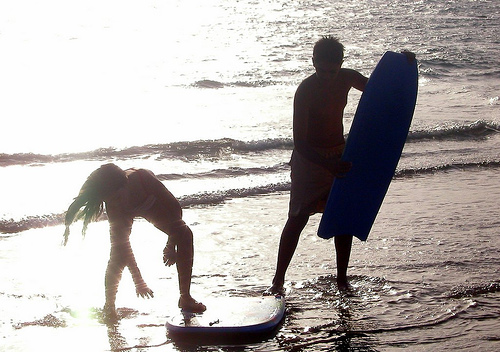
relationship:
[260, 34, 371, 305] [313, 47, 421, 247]
boy holding board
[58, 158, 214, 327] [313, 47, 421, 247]
girl has foot on board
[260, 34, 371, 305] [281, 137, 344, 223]
boy wearing shorts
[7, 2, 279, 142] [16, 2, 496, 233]
reflection on water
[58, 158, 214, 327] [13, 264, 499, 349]
girl standing on beach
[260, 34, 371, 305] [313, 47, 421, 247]
boy standing with board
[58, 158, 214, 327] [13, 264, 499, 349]
girl on beach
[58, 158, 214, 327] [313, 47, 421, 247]
girl reaches for board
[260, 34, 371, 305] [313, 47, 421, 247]
boy has a board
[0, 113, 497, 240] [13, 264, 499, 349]
waves crash on beach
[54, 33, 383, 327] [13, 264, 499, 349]
boy and girl are on beach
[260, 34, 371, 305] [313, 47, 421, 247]
boy holding a board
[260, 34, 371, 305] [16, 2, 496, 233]
boy has feet i water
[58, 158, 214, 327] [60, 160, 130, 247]
girl has hair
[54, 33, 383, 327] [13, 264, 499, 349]
boy and girl are at beach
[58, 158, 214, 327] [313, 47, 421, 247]
girl has board